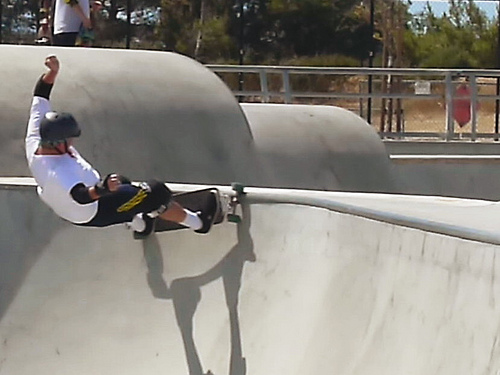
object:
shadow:
[140, 200, 257, 375]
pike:
[1, 173, 500, 375]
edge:
[1, 181, 500, 252]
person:
[50, 0, 96, 47]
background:
[0, 0, 496, 168]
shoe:
[136, 210, 157, 236]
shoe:
[194, 188, 220, 234]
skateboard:
[131, 181, 246, 241]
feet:
[131, 189, 220, 238]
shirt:
[25, 96, 100, 224]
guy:
[24, 54, 220, 237]